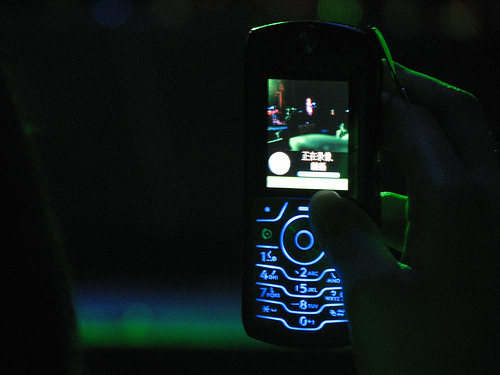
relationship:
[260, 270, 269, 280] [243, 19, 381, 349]
number on cell phone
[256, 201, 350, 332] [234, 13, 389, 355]
button on cell phone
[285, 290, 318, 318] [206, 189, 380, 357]
eight on keypad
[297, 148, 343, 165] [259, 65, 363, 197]
asian text on screen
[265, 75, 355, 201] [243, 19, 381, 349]
screen on cell phone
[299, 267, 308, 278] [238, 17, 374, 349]
number on cell phone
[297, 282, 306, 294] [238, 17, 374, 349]
number on cell phone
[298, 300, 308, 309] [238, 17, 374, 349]
number on cell phone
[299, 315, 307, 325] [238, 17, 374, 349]
number on cell phone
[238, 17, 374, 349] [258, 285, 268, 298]
cell phone has number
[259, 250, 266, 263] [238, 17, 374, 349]
number on cell phone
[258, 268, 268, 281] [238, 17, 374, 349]
number on cell phone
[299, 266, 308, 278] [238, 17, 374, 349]
number on cell phone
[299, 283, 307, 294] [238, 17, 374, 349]
number on cell phone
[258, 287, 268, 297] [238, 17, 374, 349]
number on cell phone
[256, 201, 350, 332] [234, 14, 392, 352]
button on cellphone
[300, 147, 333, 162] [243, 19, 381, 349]
logo on cell phone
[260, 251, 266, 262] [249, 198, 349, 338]
number on keypad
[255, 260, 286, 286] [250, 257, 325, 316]
4 on keypad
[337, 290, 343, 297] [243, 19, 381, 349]
number on cell phone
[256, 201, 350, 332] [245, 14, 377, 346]
button attached to cellphone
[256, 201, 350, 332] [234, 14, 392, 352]
button attached to cellphone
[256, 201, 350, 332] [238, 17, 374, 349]
button attached to cell phone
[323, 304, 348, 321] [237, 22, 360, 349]
button attached to cellphone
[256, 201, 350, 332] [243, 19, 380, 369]
button attached to cellphone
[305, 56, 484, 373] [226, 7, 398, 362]
hand holding phone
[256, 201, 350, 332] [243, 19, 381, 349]
button attached to cell phone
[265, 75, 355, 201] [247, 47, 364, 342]
screen built into phone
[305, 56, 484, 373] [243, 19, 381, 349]
hand holding cell phone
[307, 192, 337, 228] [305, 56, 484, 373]
nail growing on hand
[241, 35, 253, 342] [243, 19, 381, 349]
phoneedge bordering cell phone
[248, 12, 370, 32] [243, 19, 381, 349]
phoneedge bordering cell phone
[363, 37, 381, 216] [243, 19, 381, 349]
phoneedge bordering cell phone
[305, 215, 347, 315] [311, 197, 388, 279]
edge lining finger